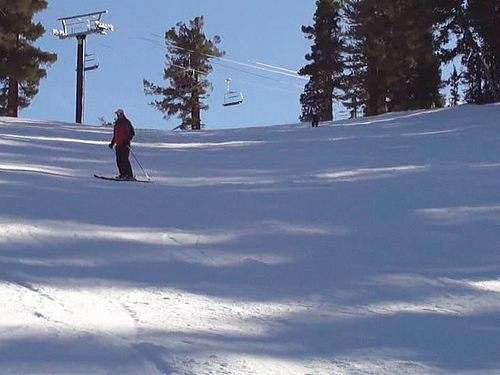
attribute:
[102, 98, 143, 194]
skier — lone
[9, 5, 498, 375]
day — sunny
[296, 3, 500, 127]
trees — larges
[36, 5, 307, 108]
ski lift — crossing, blue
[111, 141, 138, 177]
pants — black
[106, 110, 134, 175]
suit — black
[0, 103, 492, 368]
slope — snowy, powdery